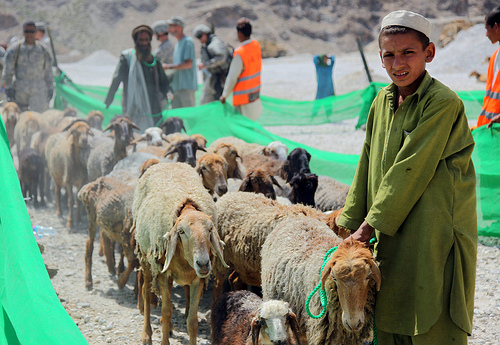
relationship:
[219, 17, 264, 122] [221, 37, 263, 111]
man has a safety vest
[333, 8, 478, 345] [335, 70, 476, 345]
boy has on a clothes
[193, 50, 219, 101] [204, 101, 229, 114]
soldier wearing a helmet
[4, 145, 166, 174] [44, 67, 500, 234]
part of fences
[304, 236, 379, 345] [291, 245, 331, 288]
green rope around sheep neck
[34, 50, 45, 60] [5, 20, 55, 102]
sunglasses on man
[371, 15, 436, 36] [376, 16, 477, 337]
boy wearing a hat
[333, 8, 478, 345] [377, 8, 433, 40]
boy has a hat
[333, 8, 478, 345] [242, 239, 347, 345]
boy holding sheep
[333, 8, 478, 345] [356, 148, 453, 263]
boy has clothes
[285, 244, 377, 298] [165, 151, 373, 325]
wire around sheep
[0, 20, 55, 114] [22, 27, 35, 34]
man wearing sunglasses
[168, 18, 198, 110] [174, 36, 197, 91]
man has a shirt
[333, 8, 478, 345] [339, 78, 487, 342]
boy wears clothes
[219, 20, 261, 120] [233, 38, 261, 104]
man wears a vest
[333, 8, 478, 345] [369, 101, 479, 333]
boy wearing cloths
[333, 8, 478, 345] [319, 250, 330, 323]
boy holding rope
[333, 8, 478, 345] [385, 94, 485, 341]
boy wearing robe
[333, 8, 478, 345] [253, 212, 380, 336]
boy holding sheep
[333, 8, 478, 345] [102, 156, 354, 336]
boy herding sheep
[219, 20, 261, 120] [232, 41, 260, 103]
man wearing vest